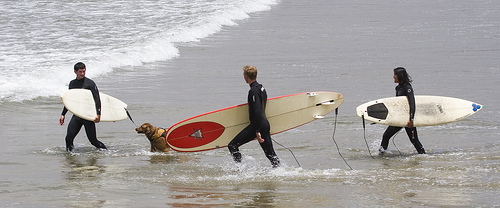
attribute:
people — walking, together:
[58, 63, 427, 168]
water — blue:
[0, 0, 499, 207]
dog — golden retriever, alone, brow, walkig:
[135, 123, 172, 152]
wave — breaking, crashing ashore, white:
[0, 0, 278, 101]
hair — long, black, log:
[393, 67, 410, 85]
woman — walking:
[377, 67, 426, 154]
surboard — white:
[355, 97, 482, 128]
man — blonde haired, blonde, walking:
[228, 66, 280, 167]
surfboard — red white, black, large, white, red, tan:
[163, 91, 344, 152]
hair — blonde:
[243, 65, 258, 80]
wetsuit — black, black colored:
[230, 79, 280, 165]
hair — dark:
[73, 62, 86, 71]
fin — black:
[369, 119, 377, 127]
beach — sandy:
[1, 3, 499, 206]